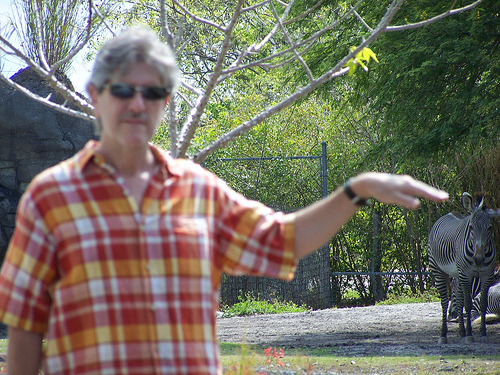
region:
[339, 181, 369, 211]
The watch on the man's wrist.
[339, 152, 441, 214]
The man's right hand.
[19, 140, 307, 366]
The plaid shirt the man is wearing.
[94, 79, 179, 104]
The sunglasses the man is wearing.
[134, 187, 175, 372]
The buttons on the man's shirt.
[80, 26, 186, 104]
The gray of the man.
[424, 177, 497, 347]
The zebra to the right of the man.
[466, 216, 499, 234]
The eyes of the zebra.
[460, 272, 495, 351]
The front legs of the zebra.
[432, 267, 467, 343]
The back legs of the zebra.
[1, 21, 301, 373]
Man is wearing checkered shirt.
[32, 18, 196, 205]
The man is wearing sunglasses.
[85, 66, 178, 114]
The sunglasses are dark.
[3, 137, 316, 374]
The shirt has sleeves.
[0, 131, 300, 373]
The shirt has a collar.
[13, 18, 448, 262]
Man is wearing watch.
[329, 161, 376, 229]
The watchband is black.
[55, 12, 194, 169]
The man has hair.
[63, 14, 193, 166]
Man's hair is gray.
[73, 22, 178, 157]
The man has a moustache.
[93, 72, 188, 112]
The person is wearing glasses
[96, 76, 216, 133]
The glasses have black frames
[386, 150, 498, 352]
Zebra is staring at the person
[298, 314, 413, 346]
No grass right here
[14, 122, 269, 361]
The shirt is patterned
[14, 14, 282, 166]
It is sunny outside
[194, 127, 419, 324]
Gates are around the area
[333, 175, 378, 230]
Person is wearing a watch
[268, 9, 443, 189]
Trees outside the gate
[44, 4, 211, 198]
The man is old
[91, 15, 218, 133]
man has grey hair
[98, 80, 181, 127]
man is wearing glasses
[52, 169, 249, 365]
man has orange and red shirt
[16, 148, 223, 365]
man's shirt is collared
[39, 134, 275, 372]
man's shirt is checked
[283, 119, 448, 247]
man wears watch on left wrist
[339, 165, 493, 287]
man points at zebra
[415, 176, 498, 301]
zebra is black and white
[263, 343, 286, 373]
red flowers on ground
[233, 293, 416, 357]
grey ground beside zebra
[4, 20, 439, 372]
Man in sunglasses with arm stretched out.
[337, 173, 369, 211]
Black watch band worn by man.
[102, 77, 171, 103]
Dark sunglasses worn by man.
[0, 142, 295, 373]
White, yellow, and red shirt worn by man.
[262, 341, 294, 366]
A bunch of red flowers together in the middle of the field.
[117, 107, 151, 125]
Man's white and black mustache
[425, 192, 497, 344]
Zebra stand in the shade.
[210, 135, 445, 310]
Metal fence behind the zebras.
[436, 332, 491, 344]
Four grey Zebra hooves.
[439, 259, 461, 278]
Zebra's bright white belly